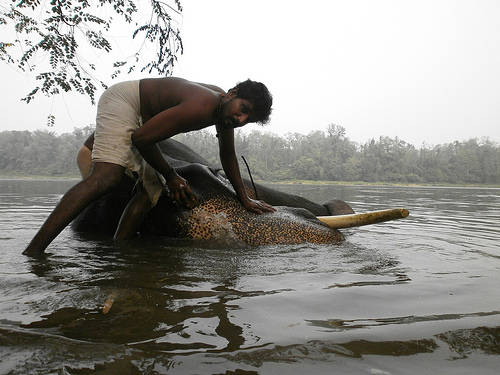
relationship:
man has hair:
[22, 79, 275, 257] [234, 78, 274, 127]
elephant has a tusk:
[73, 129, 357, 255] [315, 207, 410, 231]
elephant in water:
[73, 129, 357, 255] [0, 178, 498, 374]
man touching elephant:
[22, 79, 275, 257] [73, 129, 357, 255]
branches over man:
[0, 0, 184, 129] [22, 79, 275, 257]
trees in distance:
[0, 122, 499, 190] [1, 124, 499, 191]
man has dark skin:
[22, 79, 275, 257] [22, 78, 277, 264]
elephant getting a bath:
[73, 129, 357, 255] [174, 187, 203, 211]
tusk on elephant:
[315, 207, 410, 231] [73, 129, 357, 255]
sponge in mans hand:
[174, 186, 200, 211] [166, 167, 196, 208]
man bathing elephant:
[22, 79, 275, 257] [73, 129, 357, 255]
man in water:
[22, 79, 275, 257] [0, 178, 498, 374]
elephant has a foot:
[73, 129, 357, 255] [324, 199, 356, 218]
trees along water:
[0, 122, 499, 190] [0, 178, 498, 374]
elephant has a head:
[73, 129, 357, 255] [123, 160, 410, 277]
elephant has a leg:
[73, 129, 357, 255] [180, 152, 356, 216]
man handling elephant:
[22, 79, 275, 257] [73, 129, 357, 255]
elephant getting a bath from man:
[73, 129, 357, 255] [22, 79, 275, 257]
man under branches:
[22, 79, 275, 257] [0, 0, 184, 129]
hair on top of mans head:
[234, 78, 274, 127] [123, 160, 410, 277]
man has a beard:
[22, 79, 275, 257] [219, 97, 240, 131]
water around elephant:
[0, 178, 498, 374] [73, 129, 357, 255]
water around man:
[0, 178, 498, 374] [22, 79, 275, 257]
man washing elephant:
[22, 79, 275, 257] [73, 129, 357, 255]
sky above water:
[0, 1, 498, 154] [0, 178, 498, 374]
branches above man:
[0, 0, 184, 129] [22, 79, 275, 257]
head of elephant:
[123, 160, 410, 277] [73, 129, 357, 255]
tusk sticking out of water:
[315, 207, 410, 231] [0, 178, 498, 374]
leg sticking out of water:
[180, 152, 356, 216] [0, 178, 498, 374]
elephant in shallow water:
[73, 129, 357, 255] [0, 178, 498, 374]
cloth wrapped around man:
[91, 78, 166, 206] [22, 79, 275, 257]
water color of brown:
[0, 178, 498, 374] [1, 180, 499, 374]